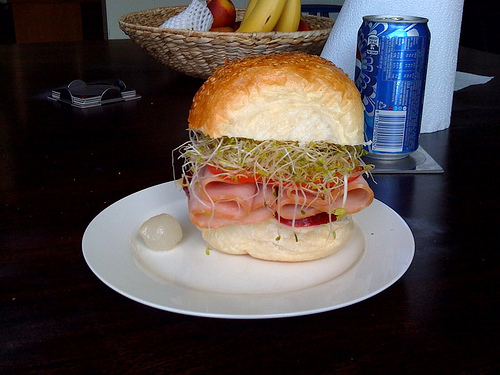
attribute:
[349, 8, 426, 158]
can — blue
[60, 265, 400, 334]
clock — round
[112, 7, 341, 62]
basket — light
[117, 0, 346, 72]
basket — fruit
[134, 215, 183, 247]
pearl onion — large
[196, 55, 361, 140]
bun — white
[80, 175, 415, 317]
plate — white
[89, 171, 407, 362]
plate — white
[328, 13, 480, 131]
towels — paper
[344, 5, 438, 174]
can — blue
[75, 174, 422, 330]
plate — white